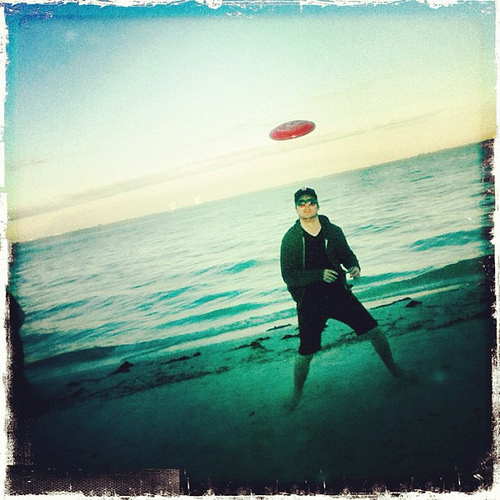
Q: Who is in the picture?
A: A man.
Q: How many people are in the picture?
A: One.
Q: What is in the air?
A: A frisbee.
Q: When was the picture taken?
A: During the day.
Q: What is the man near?
A: The water.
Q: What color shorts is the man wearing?
A: Black.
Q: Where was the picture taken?
A: At the beach.